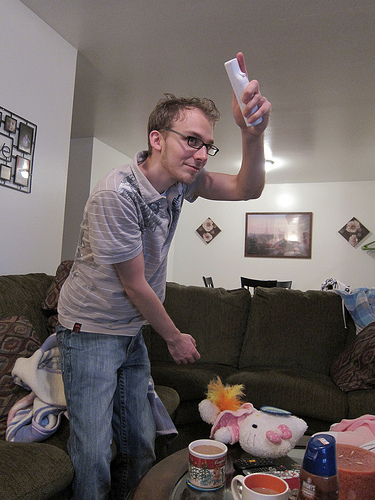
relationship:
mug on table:
[184, 434, 230, 491] [133, 432, 370, 494]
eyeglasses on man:
[153, 122, 219, 158] [59, 44, 271, 497]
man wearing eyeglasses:
[59, 44, 271, 497] [149, 122, 221, 161]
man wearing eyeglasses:
[59, 44, 271, 497] [153, 122, 219, 158]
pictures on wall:
[190, 204, 367, 262] [173, 184, 371, 287]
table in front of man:
[133, 432, 370, 494] [59, 44, 271, 497]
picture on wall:
[1, 105, 40, 196] [4, 2, 78, 276]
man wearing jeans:
[59, 44, 271, 497] [58, 321, 162, 498]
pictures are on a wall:
[190, 204, 367, 262] [148, 175, 367, 292]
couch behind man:
[8, 265, 370, 494] [59, 44, 271, 497]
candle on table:
[327, 442, 369, 496] [130, 423, 326, 498]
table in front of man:
[133, 432, 370, 499] [122, 87, 259, 200]